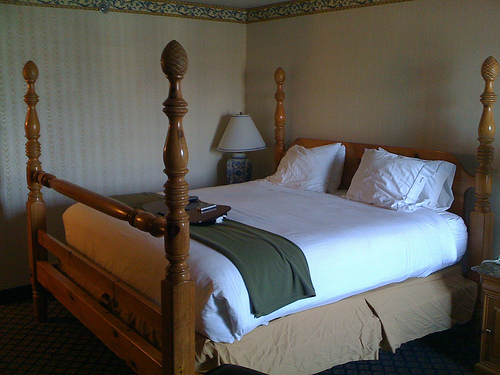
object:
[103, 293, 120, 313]
mark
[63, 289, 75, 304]
mark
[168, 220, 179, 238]
mark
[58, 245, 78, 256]
mark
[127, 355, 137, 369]
mark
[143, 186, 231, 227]
tray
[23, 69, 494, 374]
bed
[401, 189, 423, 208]
ground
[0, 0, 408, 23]
wallpaper border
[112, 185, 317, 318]
blanket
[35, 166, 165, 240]
pole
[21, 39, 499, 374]
bed frame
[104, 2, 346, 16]
wallpaper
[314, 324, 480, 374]
carpet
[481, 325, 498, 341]
knob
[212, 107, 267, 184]
lamp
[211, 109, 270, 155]
white top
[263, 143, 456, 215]
four pillows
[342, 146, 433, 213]
pillow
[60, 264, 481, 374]
bedsheets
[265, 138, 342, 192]
pillow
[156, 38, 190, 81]
post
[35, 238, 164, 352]
cabinet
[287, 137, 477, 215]
headboard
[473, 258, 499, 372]
table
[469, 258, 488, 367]
edge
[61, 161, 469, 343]
mattress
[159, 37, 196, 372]
tall stand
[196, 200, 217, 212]
items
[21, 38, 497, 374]
wood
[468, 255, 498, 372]
night stand